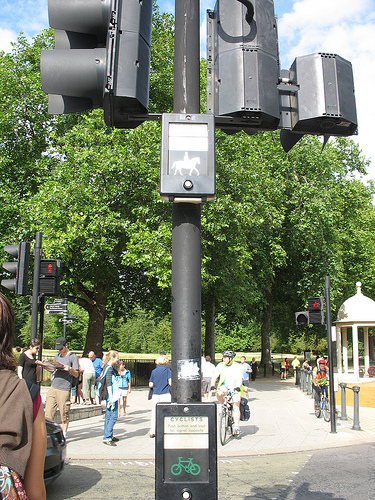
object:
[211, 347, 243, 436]
man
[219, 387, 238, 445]
bike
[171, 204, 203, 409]
pole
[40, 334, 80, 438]
guy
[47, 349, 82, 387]
teeshirt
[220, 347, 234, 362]
helmet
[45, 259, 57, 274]
light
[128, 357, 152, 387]
fence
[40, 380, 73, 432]
trouser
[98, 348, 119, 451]
woman